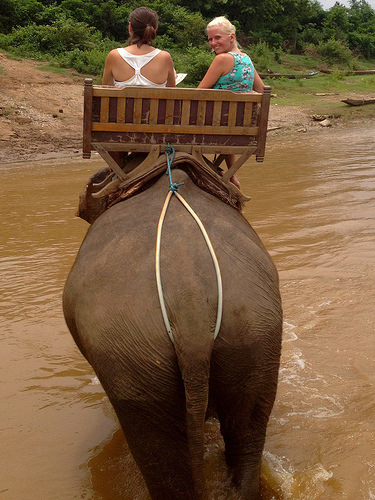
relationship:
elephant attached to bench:
[51, 162, 299, 496] [78, 74, 271, 206]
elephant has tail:
[51, 162, 299, 496] [174, 342, 212, 499]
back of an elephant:
[218, 53, 260, 90] [51, 162, 299, 496]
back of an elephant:
[103, 47, 172, 82] [51, 162, 299, 496]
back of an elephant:
[60, 205, 281, 493] [51, 162, 299, 496]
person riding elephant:
[195, 15, 263, 92] [75, 143, 288, 491]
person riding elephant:
[100, 7, 176, 88] [75, 143, 288, 491]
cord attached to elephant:
[154, 142, 223, 345] [51, 162, 299, 496]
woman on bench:
[194, 13, 267, 191] [78, 74, 271, 206]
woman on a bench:
[96, 5, 177, 85] [77, 75, 269, 192]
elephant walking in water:
[51, 162, 299, 496] [277, 157, 360, 315]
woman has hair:
[194, 13, 267, 191] [205, 13, 244, 55]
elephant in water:
[51, 162, 299, 496] [7, 112, 373, 465]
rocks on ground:
[310, 110, 340, 130] [0, 64, 371, 145]